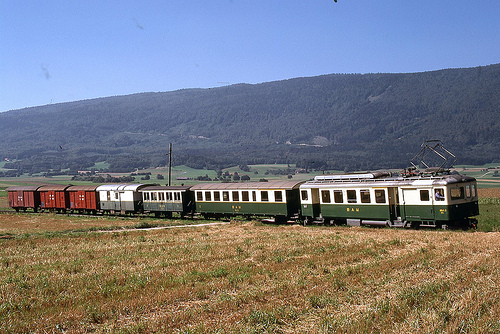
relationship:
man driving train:
[434, 187, 444, 201] [7, 171, 480, 232]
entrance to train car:
[389, 186, 400, 226] [298, 168, 481, 232]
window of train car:
[450, 186, 465, 200] [298, 168, 481, 232]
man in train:
[434, 187, 444, 201] [7, 171, 480, 232]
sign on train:
[232, 204, 243, 213] [7, 171, 480, 232]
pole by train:
[165, 142, 173, 186] [7, 171, 480, 232]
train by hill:
[7, 171, 480, 232] [0, 63, 499, 164]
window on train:
[334, 190, 345, 204] [7, 171, 480, 232]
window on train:
[346, 189, 358, 204] [7, 171, 480, 232]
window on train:
[450, 186, 465, 200] [7, 171, 480, 232]